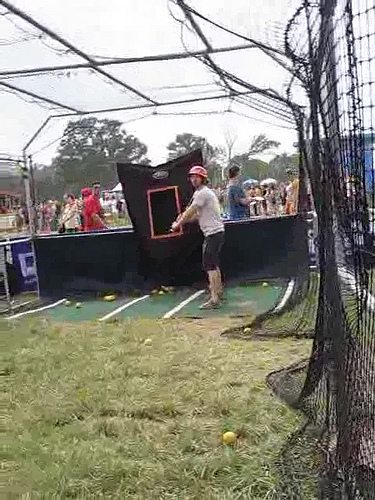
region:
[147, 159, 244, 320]
person in red helmet holding baseball bat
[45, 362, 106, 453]
blurred patch of grass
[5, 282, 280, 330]
white lines drawn on ground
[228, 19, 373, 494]
black net in exterior batting cage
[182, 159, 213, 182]
hard red helmet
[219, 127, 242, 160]
brown leafless tree branches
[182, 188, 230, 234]
white short sleeve shirt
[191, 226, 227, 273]
back shorts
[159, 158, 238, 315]
man practicing tennis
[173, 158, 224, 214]
man wears a red helmet on head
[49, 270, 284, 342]
balls on the floor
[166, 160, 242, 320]
man holds a tennis racket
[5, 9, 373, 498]
man is inside a fenced place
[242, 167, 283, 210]
people holding umbrellas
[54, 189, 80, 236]
woman holds a black purse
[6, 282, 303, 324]
white lines on floor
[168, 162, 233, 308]
man wears black pants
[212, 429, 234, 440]
yellow ball on ground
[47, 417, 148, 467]
lots of green grass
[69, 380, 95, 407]
green leaf in green grass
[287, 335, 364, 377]
black mesh at side of pen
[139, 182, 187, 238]
pink square in the pne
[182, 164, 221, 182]
large pink helmet on head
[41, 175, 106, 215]
people standing out in the open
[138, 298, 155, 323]
green color on the ground of the enclosure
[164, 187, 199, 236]
bat in man's hand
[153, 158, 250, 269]
man standing in the enclosure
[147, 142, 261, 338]
a man is in a batters cage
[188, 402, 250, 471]
a ball on the grass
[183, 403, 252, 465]
the ball is yellow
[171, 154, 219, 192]
the man is wearing a helmet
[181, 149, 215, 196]
the helmet is red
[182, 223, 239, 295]
man is wearing shorts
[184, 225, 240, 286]
the shorts are black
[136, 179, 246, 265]
the man is holding a bat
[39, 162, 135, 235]
people in the background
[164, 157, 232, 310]
person holding a base ball bat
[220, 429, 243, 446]
yellow ball lying in the grass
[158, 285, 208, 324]
white line painted on the ground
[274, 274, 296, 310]
white line painted on the ground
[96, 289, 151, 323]
white line painted on the ground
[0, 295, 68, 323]
white line painted on the ground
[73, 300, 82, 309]
green ball lying on the ground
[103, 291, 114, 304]
green ball lying on the ground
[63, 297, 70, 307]
green ball lying on the ground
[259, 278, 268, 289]
green ball lying on the ground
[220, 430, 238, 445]
a yellow base ball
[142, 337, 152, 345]
a yellow base ball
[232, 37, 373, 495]
a wall of black safety netting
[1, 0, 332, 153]
a black safety net ceiling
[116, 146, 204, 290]
a black safety bag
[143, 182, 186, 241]
a red square made of tape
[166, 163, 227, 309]
a man holding a baseball bat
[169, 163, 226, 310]
a man wearing a red helmet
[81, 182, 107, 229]
a man wearing a red shirt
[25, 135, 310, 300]
a group of people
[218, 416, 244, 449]
a ball on the ground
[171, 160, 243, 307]
man holding a bat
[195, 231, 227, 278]
a pair of shorts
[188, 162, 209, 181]
a red baseball helmet